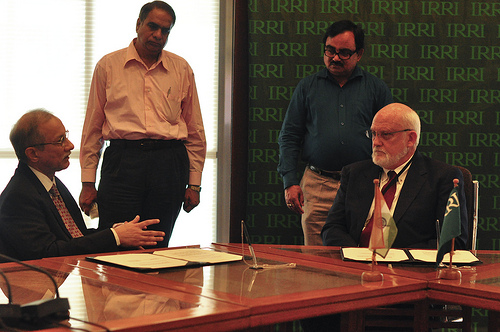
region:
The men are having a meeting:
[20, 5, 495, 321]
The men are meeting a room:
[10, 11, 485, 301]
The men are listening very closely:
[205, 15, 475, 305]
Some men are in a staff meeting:
[0, 0, 490, 315]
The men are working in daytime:
[15, 1, 485, 321]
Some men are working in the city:
[0, 7, 490, 309]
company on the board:
[251, 18, 281, 34]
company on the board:
[370, 45, 408, 60]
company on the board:
[416, 83, 458, 106]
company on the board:
[242, 17, 290, 44]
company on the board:
[389, 18, 439, 43]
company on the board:
[440, 19, 487, 44]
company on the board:
[409, 126, 461, 153]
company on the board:
[243, 189, 280, 210]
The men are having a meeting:
[5, 5, 491, 316]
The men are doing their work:
[11, 7, 492, 318]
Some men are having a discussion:
[11, 16, 491, 319]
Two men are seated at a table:
[10, 2, 485, 317]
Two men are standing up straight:
[20, 5, 491, 320]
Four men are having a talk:
[1, 10, 482, 323]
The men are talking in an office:
[11, 10, 487, 320]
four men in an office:
[0, 0, 473, 252]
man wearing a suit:
[0, 106, 166, 256]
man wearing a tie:
[1, 106, 166, 258]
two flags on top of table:
[357, 178, 466, 280]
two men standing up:
[78, 0, 395, 243]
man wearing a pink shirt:
[84, 0, 207, 253]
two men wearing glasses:
[282, 20, 468, 245]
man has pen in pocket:
[78, 0, 206, 250]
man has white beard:
[318, 102, 473, 245]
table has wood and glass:
[3, 238, 498, 329]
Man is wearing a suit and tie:
[1, 104, 169, 261]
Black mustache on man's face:
[327, 54, 348, 73]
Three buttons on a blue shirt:
[334, 94, 350, 152]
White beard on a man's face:
[368, 140, 413, 170]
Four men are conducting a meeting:
[1, 0, 498, 326]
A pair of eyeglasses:
[362, 122, 415, 142]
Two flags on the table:
[354, 173, 472, 287]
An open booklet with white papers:
[77, 240, 251, 278]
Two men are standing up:
[76, 0, 397, 243]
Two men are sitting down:
[2, 98, 474, 259]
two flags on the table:
[358, 174, 467, 283]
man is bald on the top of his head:
[369, 101, 424, 166]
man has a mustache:
[325, 53, 351, 72]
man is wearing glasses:
[2, 109, 73, 166]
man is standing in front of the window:
[79, 0, 205, 251]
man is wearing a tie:
[50, 174, 83, 246]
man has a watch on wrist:
[190, 179, 201, 197]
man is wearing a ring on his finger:
[281, 187, 311, 216]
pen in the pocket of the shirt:
[160, 75, 183, 117]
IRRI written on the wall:
[393, 20, 436, 43]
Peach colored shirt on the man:
[76, 36, 207, 192]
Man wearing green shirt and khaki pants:
[278, 17, 396, 244]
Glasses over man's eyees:
[318, 40, 359, 60]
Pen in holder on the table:
[236, 213, 264, 273]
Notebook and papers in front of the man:
[338, 242, 478, 266]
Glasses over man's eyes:
[363, 122, 397, 142]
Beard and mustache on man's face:
[368, 144, 398, 164]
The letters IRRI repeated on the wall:
[232, 2, 496, 240]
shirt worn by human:
[28, 167, 62, 199]